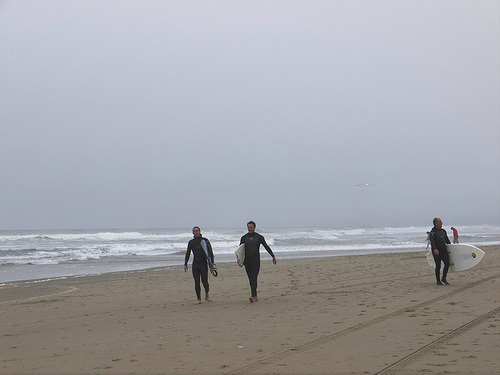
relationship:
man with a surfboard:
[184, 225, 215, 304] [193, 238, 221, 278]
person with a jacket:
[446, 221, 464, 249] [452, 228, 458, 238]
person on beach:
[423, 228, 433, 256] [4, 229, 479, 352]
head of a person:
[416, 223, 439, 238] [424, 231, 433, 251]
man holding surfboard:
[422, 212, 454, 286] [420, 239, 484, 274]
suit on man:
[183, 235, 214, 301] [172, 221, 222, 305]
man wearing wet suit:
[236, 220, 277, 303] [222, 232, 275, 300]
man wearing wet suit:
[422, 212, 454, 286] [422, 223, 454, 286]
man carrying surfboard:
[172, 221, 222, 305] [196, 238, 216, 276]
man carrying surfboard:
[236, 220, 277, 303] [226, 234, 250, 268]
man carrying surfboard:
[428, 217, 452, 286] [417, 235, 482, 270]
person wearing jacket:
[450, 226, 459, 244] [447, 227, 464, 243]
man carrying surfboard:
[236, 220, 277, 303] [230, 237, 258, 280]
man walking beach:
[184, 225, 215, 304] [3, 303, 221, 362]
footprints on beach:
[292, 268, 394, 309] [0, 317, 273, 356]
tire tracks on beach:
[233, 273, 500, 374] [4, 283, 214, 364]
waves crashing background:
[94, 222, 175, 251] [4, 221, 484, 240]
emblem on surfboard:
[455, 245, 477, 269] [416, 240, 484, 278]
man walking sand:
[236, 220, 277, 303] [209, 300, 410, 370]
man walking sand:
[236, 220, 277, 303] [126, 293, 398, 367]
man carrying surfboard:
[428, 217, 452, 286] [425, 238, 482, 275]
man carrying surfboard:
[428, 217, 452, 286] [422, 236, 484, 283]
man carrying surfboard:
[234, 220, 278, 302] [234, 243, 255, 273]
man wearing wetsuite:
[236, 220, 277, 303] [239, 231, 272, 295]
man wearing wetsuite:
[236, 220, 277, 303] [238, 230, 268, 300]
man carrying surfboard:
[236, 220, 277, 303] [231, 238, 251, 276]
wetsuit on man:
[235, 234, 281, 289] [229, 219, 275, 289]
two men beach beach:
[161, 201, 293, 294] [37, 216, 498, 357]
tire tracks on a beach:
[351, 275, 479, 371] [52, 200, 482, 363]